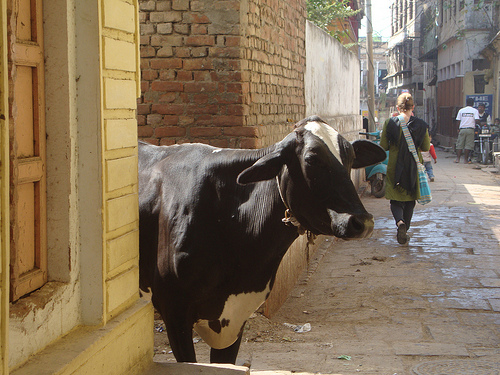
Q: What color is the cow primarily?
A: Black.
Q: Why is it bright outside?
A: Its daytime.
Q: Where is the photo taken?
A: Street.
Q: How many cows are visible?
A: One.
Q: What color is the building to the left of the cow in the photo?
A: Yellow.